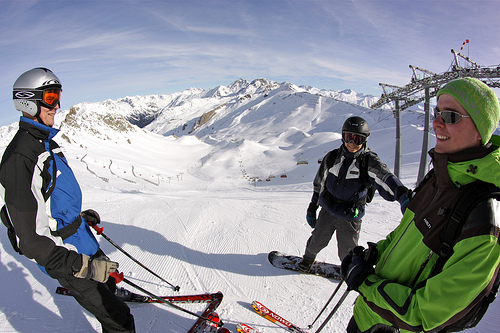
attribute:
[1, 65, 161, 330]
skiier — downhill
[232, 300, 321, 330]
skiis — downhill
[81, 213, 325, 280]
shadow — snowboarder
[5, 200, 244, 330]
shadows — skiiers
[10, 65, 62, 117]
helmet — grey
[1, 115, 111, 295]
jacket — blue, black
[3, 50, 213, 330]
man — skiing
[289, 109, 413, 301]
man — snowboarding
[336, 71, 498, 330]
jacket — lime green, black, green, ski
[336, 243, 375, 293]
gloves — black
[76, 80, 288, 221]
mountain — white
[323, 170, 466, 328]
suit — green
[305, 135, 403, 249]
suit — black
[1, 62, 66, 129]
helmet — gray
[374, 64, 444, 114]
ski lift — metal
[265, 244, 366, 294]
snow board — black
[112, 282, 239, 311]
snow ski — black, red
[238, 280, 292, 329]
snow ski — orange, red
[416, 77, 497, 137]
toboggan — bright green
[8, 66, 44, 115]
helmet — silver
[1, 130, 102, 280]
jacket — blue, white, black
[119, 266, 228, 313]
skis — red, black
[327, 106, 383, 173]
helmet — black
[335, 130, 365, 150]
ski goggles — black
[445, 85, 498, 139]
hat — green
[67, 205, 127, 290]
gloves — grey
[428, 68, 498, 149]
hat — green